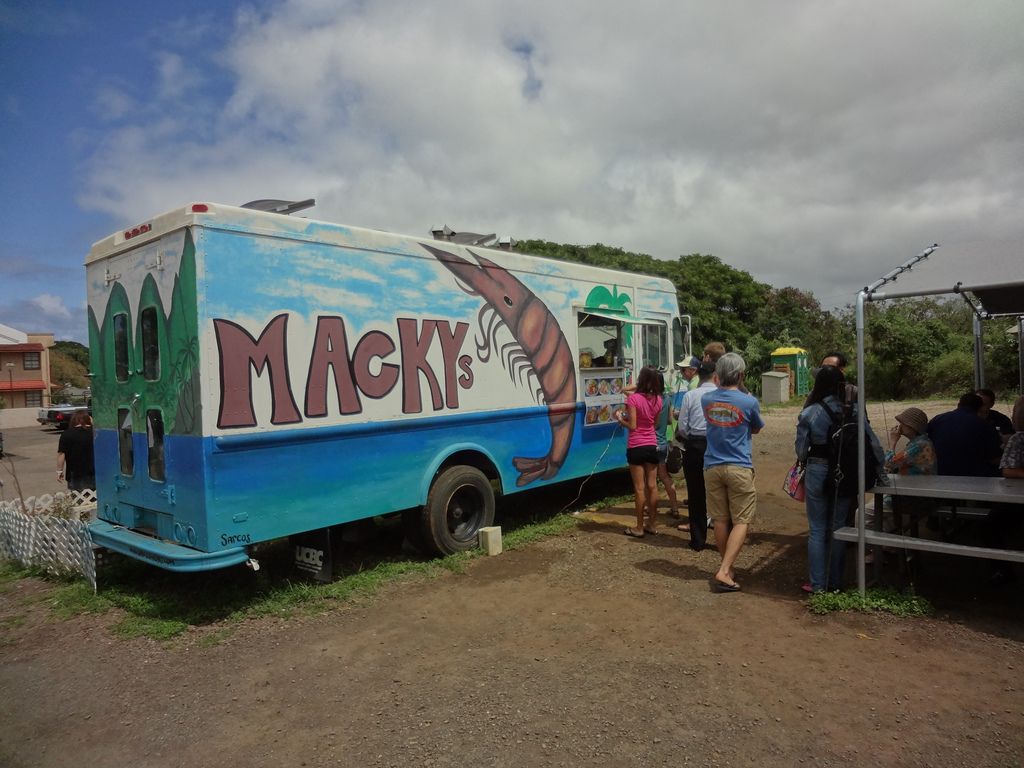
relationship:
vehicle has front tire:
[96, 184, 777, 580] [657, 428, 689, 493]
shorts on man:
[701, 467, 763, 531] [698, 360, 763, 583]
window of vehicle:
[128, 411, 174, 484] [103, 148, 806, 591]